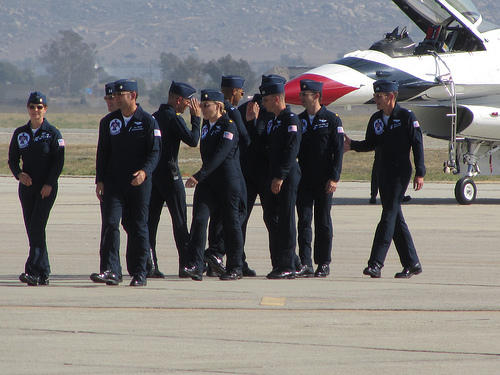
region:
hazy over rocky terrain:
[3, 2, 498, 66]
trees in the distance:
[1, 27, 278, 95]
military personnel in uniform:
[11, 74, 424, 284]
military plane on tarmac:
[248, 0, 499, 206]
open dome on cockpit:
[380, 1, 497, 57]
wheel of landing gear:
[453, 140, 496, 202]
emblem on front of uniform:
[108, 116, 120, 135]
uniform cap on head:
[26, 91, 49, 121]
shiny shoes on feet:
[91, 270, 146, 286]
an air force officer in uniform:
[5, 88, 67, 288]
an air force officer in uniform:
[86, 74, 161, 291]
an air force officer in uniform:
[360, 76, 426, 282]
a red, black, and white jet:
[278, 2, 499, 198]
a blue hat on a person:
[24, 89, 51, 108]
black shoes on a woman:
[16, 267, 54, 284]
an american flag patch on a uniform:
[220, 126, 234, 140]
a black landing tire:
[453, 172, 478, 207]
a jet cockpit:
[358, 2, 488, 65]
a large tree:
[33, 24, 98, 105]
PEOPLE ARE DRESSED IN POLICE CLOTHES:
[12, 20, 444, 265]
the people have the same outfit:
[54, 78, 448, 263]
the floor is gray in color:
[198, 315, 290, 374]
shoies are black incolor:
[275, 264, 339, 302]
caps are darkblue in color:
[97, 73, 149, 95]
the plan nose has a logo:
[282, 53, 411, 120]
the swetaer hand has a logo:
[133, 118, 175, 163]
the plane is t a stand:
[372, 15, 497, 159]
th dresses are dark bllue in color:
[86, 115, 178, 263]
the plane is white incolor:
[412, 11, 499, 120]